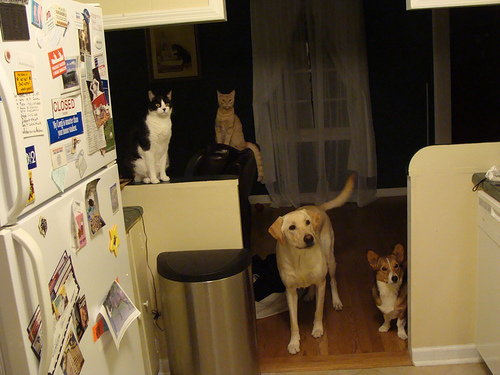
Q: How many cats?
A: Two.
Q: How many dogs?
A: Two.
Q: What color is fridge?
A: White.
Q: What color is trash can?
A: Silver.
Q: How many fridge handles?
A: Two.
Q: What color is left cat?
A: White and black.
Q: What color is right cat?
A: Orange.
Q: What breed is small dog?
A: Corgi.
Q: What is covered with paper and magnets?
A: The refrigerator is covered with papers and magnets.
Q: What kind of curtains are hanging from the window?
A: There are sheer curtains hanging from the windows.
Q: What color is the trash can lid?
A: The trash can lid is black.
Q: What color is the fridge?
A: The fridge is white.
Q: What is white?
A: The curtain is white.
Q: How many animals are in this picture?
A: 4.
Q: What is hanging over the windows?
A: Curtains.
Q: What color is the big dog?
A: Yellow.